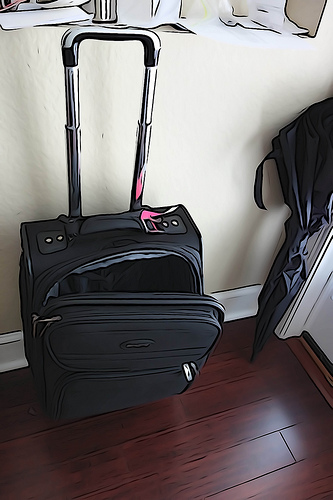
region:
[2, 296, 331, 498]
Laminate wooden flooring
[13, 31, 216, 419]
Open black suitcase with handle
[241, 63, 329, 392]
Black umbrella standing in the corner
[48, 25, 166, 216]
Handle of the black suitcase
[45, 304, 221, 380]
One of two front pockets of the suitcase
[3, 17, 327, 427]
Suitcase and umbrella side by side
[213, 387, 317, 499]
Reflection of light on the floor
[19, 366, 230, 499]
Shadow of the suitcase on the floor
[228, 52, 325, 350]
Shadow of umbrella on the wall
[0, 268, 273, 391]
White baseboards behind suitcase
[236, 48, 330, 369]
long black umbrella standing against a wall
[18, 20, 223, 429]
open rolling suitcase against a wall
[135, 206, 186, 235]
pink tag on a black suitcase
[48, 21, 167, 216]
retractable handle on a rolling suitcase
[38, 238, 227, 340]
open top of rolling suitcase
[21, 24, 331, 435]
umbrella and suitcase standing by door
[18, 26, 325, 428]
umbrella and suitcase leaning against a wall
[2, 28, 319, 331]
cream colored wall behind suitcase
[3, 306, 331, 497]
dark wood floor under suitcase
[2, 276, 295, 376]
white floorboard on cream colored wall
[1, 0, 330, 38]
bottom edge of painting with black outlines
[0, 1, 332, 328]
umbrella and suitcase against tan wall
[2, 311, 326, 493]
dark brown floor of planks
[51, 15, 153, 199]
extended silver handle on back of suitcase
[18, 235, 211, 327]
unzippered main compartment showing emptiness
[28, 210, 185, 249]
black handle and side tab attachments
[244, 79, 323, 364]
black umbrella by corner door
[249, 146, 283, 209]
curved umbrella strap hanging down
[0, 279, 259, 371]
white molding at floor base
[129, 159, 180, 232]
reflection of pink and white tag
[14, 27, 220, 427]
big black bag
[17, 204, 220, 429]
black bag open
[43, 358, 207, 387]
black zip with metal holders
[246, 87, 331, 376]
big black umbrella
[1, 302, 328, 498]
mahogany wooden floor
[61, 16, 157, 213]
black and gray handle of bag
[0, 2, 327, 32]
picture hanging on wall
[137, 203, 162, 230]
fuchsia label on bag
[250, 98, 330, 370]
black umbrella beside beige wall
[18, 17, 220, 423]
black bag next to black umbrella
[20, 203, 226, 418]
one partially open black suitcase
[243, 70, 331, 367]
dark umbrella propped against wall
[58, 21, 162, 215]
one shiny metal suitcase handle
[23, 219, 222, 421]
empty black open suitcase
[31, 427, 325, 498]
section of dark wooden floorboards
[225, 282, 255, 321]
section of white household baseboard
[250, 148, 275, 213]
one dark umbrella closing tab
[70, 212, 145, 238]
one broad black umbrella handle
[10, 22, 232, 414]
one black canvas suitcase propped against wall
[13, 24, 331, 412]
dark suitcase next to dark umbrella